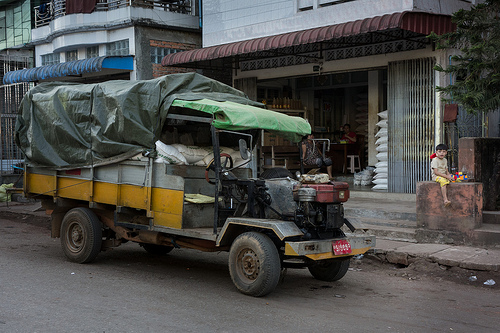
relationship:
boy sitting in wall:
[431, 143, 465, 207] [416, 182, 475, 237]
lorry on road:
[14, 72, 377, 297] [3, 226, 497, 331]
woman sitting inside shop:
[337, 122, 360, 174] [159, 10, 498, 195]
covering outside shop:
[3, 55, 131, 86] [31, 55, 136, 87]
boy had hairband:
[431, 143, 465, 207] [430, 152, 435, 159]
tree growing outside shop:
[421, 1, 499, 121] [334, 7, 457, 186]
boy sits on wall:
[431, 143, 465, 207] [411, 177, 487, 244]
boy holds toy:
[431, 143, 465, 207] [436, 152, 476, 189]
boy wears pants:
[431, 143, 465, 207] [434, 176, 452, 197]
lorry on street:
[14, 72, 377, 297] [5, 243, 480, 331]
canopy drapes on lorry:
[12, 66, 310, 175] [14, 72, 377, 297]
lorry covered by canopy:
[14, 72, 377, 297] [173, 83, 331, 155]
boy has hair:
[431, 143, 465, 207] [432, 140, 447, 152]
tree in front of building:
[421, 1, 499, 121] [160, 0, 470, 195]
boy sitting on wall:
[424, 141, 464, 197] [415, 177, 483, 245]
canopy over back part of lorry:
[13, 72, 310, 172] [14, 72, 377, 297]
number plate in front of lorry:
[332, 240, 352, 255] [14, 72, 377, 297]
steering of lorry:
[200, 156, 241, 185] [14, 72, 377, 297]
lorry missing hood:
[14, 72, 377, 297] [224, 169, 363, 244]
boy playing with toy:
[431, 143, 465, 207] [448, 170, 466, 181]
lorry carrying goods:
[14, 72, 377, 297] [104, 110, 265, 176]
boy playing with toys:
[431, 143, 465, 207] [452, 164, 469, 184]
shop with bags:
[204, 21, 461, 240] [305, 169, 371, 186]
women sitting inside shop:
[295, 121, 364, 176] [257, 65, 388, 174]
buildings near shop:
[24, 2, 201, 77] [164, 29, 466, 220]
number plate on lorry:
[332, 240, 354, 259] [14, 72, 377, 297]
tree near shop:
[417, 1, 499, 120] [171, 14, 455, 208]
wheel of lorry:
[60, 207, 100, 258] [14, 72, 377, 297]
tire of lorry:
[227, 231, 282, 297] [14, 72, 377, 297]